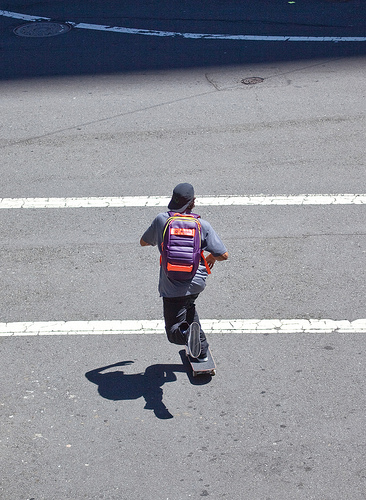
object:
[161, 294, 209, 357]
dark pants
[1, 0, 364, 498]
asphalt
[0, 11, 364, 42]
lines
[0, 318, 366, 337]
lines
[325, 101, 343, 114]
ground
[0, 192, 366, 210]
line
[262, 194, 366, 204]
paint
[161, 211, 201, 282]
backpack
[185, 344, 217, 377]
skateboard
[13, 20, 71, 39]
circle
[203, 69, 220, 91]
gutter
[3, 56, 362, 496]
street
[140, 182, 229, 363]
boy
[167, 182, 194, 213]
cap